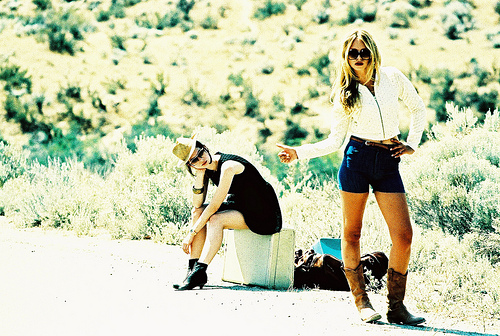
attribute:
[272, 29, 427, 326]
woman — standing, knee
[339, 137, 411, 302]
legs — woman's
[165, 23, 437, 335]
women — hitchhiking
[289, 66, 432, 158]
shirt — white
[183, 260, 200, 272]
boot — brown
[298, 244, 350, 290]
bag — brown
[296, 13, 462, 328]
woman — knee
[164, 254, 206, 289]
booties — black